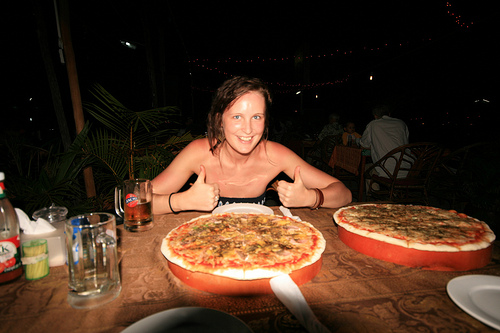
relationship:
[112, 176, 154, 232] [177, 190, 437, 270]
glass mug on table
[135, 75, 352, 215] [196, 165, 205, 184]
girl has thumb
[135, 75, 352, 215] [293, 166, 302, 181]
girl has thumb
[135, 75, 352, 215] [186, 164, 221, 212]
girl has hand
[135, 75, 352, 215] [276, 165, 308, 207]
girl has hand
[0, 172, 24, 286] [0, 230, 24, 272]
bottle has label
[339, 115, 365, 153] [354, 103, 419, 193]
child with adult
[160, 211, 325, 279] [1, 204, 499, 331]
pizza on table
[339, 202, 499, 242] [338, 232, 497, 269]
pizza on pizza tray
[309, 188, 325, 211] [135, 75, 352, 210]
braclets on girl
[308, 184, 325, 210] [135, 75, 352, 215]
braclets on girl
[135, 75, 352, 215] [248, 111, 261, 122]
girl has eye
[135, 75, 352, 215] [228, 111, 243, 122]
girl has eye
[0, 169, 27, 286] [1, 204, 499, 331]
bottle on table